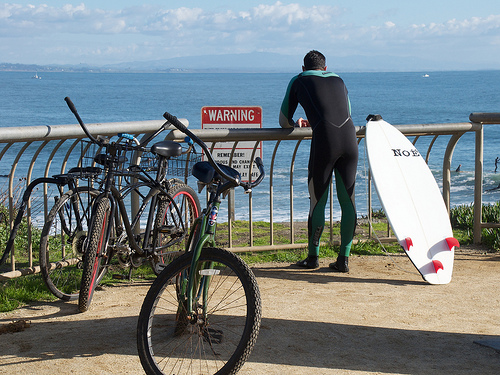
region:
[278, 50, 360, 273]
Man looking out to the ocean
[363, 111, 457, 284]
White surfboard next to man.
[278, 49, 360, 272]
Man wearing a black and teal wetsuit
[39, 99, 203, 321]
Bikes parked along the railing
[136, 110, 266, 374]
Green bike parked on the pavement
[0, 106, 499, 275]
Silver railing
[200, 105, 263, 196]
Warning sign behind railing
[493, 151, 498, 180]
Person surfing in the distance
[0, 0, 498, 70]
Clouds in the blue sky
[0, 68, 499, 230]
Blue expanse of ocean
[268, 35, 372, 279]
man looking out at the ocean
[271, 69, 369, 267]
man's wetsuit that is mostly black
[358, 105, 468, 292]
white surfboard leaning on a rail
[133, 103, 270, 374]
green bike resting on a kick stand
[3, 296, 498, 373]
long shadow in the dirt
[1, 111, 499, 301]
metal rail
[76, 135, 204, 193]
basket on a bike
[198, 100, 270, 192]
warning sign near the rail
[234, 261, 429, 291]
shadow of the surfboard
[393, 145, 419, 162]
letters on the surfboard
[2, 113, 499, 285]
a gray metal fence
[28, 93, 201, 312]
two bicycles propped against a fence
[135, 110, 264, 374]
a green bicycle standing on a stand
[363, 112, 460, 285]
a white surfboard propped on a fence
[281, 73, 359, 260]
man wearing a wet suit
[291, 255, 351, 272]
man wearing black shoes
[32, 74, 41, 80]
a white boat on the ocean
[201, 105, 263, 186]
a red and white sign on a fence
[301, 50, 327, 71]
a man with short black hair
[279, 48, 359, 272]
a man looking at the ocean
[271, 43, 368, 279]
a man wearing a wet suit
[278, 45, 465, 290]
a man standing next to a white and red surfboard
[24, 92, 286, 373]
three bikes near a gray railing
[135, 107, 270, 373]
a green bike propped on a kickstand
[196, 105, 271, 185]
a red and white warning sign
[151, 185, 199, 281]
the red wheel on a black bike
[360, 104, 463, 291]
a white and red surfboard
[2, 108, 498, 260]
a gray railing on the beach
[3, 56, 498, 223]
the blue water in an ocean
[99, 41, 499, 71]
mountains above the distant shore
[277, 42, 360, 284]
A man in a wet suit.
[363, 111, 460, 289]
A white surfboard.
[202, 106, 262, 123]
A red and white warning sign.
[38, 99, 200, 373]
Two black bicycles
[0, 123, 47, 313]
A metal bike rack.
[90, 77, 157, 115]
A body of water.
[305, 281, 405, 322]
The dry dirt ground.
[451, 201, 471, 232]
A small grassy area.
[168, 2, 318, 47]
The clouds in the sky.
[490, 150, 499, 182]
A surfer in the water.